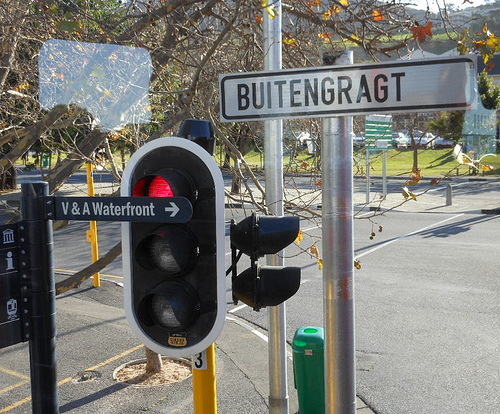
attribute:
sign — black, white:
[203, 56, 483, 123]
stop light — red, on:
[111, 133, 234, 359]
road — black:
[1, 171, 499, 327]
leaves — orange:
[240, 2, 499, 58]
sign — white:
[38, 197, 192, 221]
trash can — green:
[289, 324, 328, 413]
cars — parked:
[277, 132, 453, 149]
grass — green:
[3, 154, 499, 176]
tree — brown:
[393, 109, 462, 172]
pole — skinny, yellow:
[80, 152, 106, 287]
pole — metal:
[320, 50, 358, 414]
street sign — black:
[45, 194, 195, 224]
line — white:
[223, 212, 468, 317]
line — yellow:
[3, 340, 150, 413]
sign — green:
[364, 114, 393, 206]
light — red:
[137, 178, 182, 213]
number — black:
[190, 351, 207, 373]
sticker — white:
[195, 352, 209, 371]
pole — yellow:
[187, 342, 218, 413]